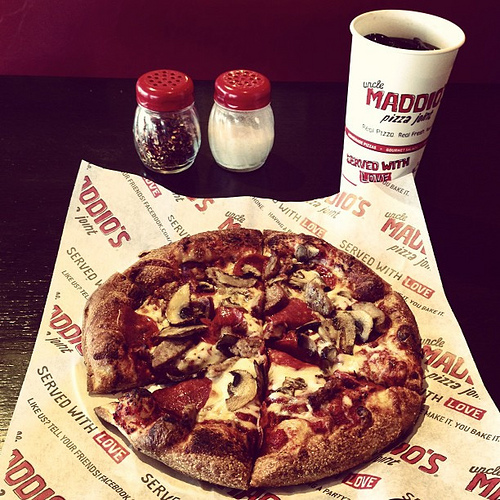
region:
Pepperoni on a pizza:
[117, 245, 410, 451]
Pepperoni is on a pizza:
[115, 241, 400, 441]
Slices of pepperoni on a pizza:
[115, 238, 396, 449]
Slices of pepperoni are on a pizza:
[111, 237, 402, 445]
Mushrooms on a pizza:
[126, 248, 407, 440]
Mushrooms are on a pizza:
[102, 240, 386, 434]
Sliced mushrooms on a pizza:
[130, 235, 403, 428]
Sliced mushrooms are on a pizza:
[127, 240, 389, 431]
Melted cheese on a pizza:
[140, 246, 397, 445]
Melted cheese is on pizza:
[140, 256, 393, 453]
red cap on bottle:
[133, 66, 190, 108]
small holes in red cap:
[147, 73, 172, 85]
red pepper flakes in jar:
[143, 127, 189, 159]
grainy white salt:
[212, 124, 264, 148]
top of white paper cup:
[335, 7, 457, 76]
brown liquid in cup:
[377, 32, 425, 47]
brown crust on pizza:
[172, 452, 233, 474]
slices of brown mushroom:
[214, 360, 319, 420]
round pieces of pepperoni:
[144, 376, 221, 412]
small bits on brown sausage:
[292, 279, 344, 316]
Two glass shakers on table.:
[135, 67, 277, 176]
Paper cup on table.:
[347, 6, 465, 199]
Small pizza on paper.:
[82, 218, 439, 485]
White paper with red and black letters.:
[0, 158, 498, 498]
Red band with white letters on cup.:
[342, 123, 432, 155]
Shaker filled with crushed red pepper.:
[112, 72, 200, 176]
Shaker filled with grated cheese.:
[208, 65, 282, 168]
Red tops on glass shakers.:
[130, 72, 271, 109]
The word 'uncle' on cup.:
[362, 78, 384, 89]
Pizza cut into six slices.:
[85, 226, 427, 495]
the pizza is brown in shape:
[80, 223, 430, 496]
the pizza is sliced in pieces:
[88, 228, 422, 481]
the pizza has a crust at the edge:
[81, 226, 423, 490]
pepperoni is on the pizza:
[272, 293, 309, 338]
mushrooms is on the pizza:
[255, 283, 288, 315]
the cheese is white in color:
[207, 356, 255, 433]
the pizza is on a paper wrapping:
[10, 167, 485, 494]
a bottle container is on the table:
[127, 67, 197, 174]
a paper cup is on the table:
[340, 11, 462, 211]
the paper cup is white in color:
[342, 12, 464, 208]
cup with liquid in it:
[351, 25, 433, 177]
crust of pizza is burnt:
[143, 420, 184, 465]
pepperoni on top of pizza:
[236, 291, 317, 327]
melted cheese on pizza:
[237, 365, 319, 377]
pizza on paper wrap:
[101, 208, 406, 498]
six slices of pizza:
[101, 263, 415, 473]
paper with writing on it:
[28, 368, 113, 477]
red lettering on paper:
[82, 198, 128, 250]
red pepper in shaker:
[124, 60, 206, 172]